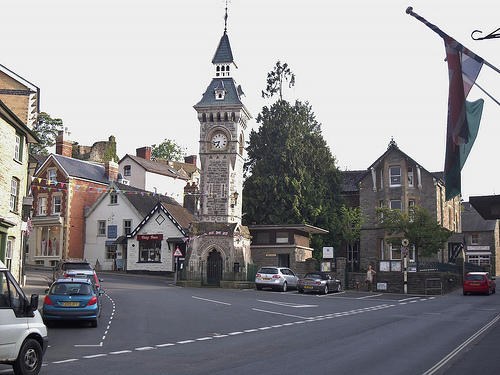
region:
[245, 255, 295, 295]
A parked silver car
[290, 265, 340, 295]
A parked grey car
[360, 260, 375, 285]
A man standing on the sidewalk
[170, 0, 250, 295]
An old clock tower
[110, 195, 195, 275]
An old small shop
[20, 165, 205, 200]
A string of multicolored flags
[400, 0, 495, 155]
A rolled up flag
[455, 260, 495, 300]
A driving red car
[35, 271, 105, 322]
A driving blue car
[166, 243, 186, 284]
A white/red road sign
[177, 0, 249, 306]
A tall clock tower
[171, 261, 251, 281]
The tower is inside of an iron fence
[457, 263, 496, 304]
A small red car driving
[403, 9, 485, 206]
A flag on a flag pole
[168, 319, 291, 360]
White lines on the street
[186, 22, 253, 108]
This is also a bell tower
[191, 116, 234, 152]
The clock reads eight thirty five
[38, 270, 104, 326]
A small blue car parked near the curb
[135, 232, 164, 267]
The window on a business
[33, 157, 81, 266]
A three story building made of brick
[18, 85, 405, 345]
The photo is of a city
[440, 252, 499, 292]
The car is red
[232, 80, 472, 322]
The tree is behind the clock tower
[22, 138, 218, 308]
There is a small white building with a red sign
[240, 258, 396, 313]
The car is silver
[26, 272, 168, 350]
A blue car is parked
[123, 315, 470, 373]
white dotted lines are on the street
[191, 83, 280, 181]
A clock is on the building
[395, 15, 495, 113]
Two flags are hanging from poles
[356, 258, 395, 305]
A woman is standing next to the building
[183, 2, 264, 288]
clock on an old tower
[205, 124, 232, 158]
white clock on old tower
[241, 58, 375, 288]
green tree behind a house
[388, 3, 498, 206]
a flag on right side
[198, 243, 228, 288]
door of tower is brown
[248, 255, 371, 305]
cars parking on parking lot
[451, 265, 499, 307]
a red car on the road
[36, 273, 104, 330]
a blue car on the road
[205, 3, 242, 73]
pointy steeple color black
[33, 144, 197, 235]
roofs of houses are black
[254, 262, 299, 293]
silver car parked on the street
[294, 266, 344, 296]
gray car parked on the street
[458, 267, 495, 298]
red car driving on the street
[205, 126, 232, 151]
white and black clock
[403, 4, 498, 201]
flags hanging on the right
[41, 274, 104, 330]
blue car parked on the side of the street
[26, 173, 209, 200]
triangles hanging from the building to the tower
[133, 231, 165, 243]
red banner above the window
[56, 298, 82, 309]
yellow license plate on the blue car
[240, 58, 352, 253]
large green tree next to the clock tower